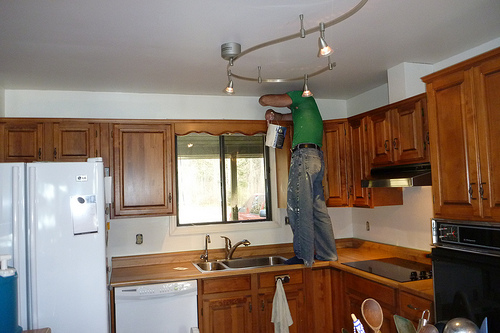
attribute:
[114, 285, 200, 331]
door — white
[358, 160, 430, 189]
hood — metal, grey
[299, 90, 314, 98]
bulb — tiny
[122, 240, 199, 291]
counter — brown, wood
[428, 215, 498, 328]
oven — black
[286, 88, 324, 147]
shirt — green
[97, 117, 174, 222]
cabinet — brown, wooden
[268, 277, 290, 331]
towel — white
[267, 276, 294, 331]
towel — white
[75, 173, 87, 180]
logo — grey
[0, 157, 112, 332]
refrigerator — white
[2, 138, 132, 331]
fridge — white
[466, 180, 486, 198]
knobs — black, metal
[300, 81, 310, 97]
light — metal